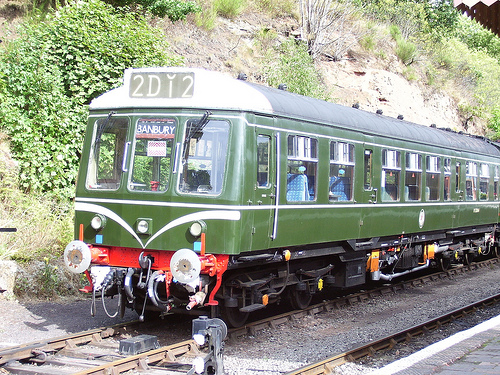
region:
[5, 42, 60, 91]
these are leaves on the tree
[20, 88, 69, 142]
these are leaves on the tree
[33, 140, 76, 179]
these are leaves on the tree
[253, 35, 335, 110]
this is a tree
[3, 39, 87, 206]
this is a tree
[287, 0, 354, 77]
this is a tree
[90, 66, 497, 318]
this is a train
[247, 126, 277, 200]
a window on the train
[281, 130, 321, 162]
a window on the train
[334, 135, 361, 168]
a window on the train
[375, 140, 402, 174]
a window on the train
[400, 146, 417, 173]
a window on the train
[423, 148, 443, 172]
a window on the train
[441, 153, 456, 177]
a window on the train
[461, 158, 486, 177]
a window on the train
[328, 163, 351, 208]
a window on the train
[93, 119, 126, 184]
the front window of a train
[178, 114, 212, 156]
the wiper of a train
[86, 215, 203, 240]
the head lights of a train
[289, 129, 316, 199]
the window of a train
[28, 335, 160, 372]
the rail of a train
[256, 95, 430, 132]
the top of a train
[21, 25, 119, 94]
green leaves of a plant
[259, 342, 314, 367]
pebbles on the side of the rail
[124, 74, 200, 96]
letters and numbers on a train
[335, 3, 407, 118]
the slope of a valley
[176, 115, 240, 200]
window of a train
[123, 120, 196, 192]
window of a train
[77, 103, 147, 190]
window of a train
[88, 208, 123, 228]
light of a train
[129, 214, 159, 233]
light of a train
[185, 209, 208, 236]
light of a train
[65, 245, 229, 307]
front of a train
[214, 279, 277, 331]
wheel of a train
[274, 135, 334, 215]
window of a train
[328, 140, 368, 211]
window of a train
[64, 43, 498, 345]
A green train on tracks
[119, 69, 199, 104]
The front train plate identifier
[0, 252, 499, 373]
The ;multiple train tracks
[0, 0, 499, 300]
The raised background hills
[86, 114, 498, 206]
The clear train windows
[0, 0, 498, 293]
The background's growing thickets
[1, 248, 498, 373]
The gravel filled tracks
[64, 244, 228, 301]
A red colored train bumper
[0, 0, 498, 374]
A passenger train on tracks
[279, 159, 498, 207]
The blue passenger seats inside the train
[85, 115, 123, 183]
a window on a train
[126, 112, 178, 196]
a window on a train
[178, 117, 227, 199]
a window on a train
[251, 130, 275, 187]
a window on a train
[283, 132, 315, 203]
a window on a train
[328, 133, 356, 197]
a window on a train